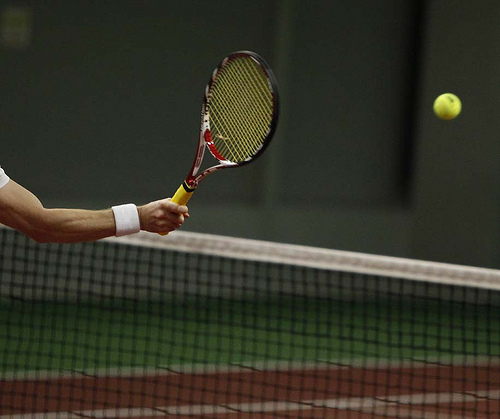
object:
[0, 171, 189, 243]
man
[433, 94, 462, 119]
ball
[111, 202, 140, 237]
wristband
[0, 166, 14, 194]
sleeve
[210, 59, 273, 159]
strings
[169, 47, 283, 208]
tennis racket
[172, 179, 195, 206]
handle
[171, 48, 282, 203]
racket